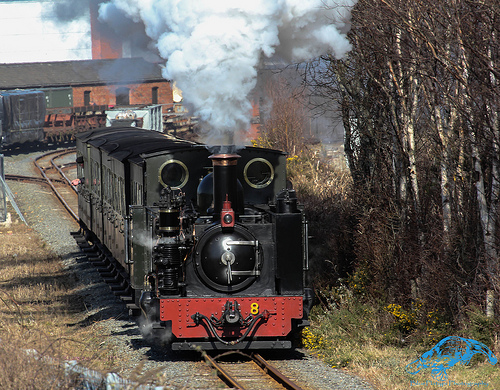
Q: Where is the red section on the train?
A: Front side.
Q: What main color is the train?
A: Black.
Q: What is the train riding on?
A: Tracks.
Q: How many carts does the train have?
A: 3.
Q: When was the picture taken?
A: Sunny day.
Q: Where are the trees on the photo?
A: Left of train.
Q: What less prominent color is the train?
A: Red.